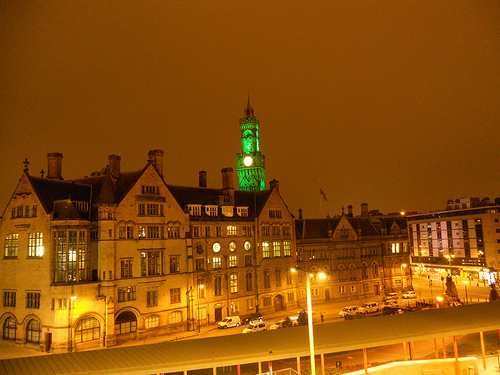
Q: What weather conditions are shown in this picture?
A: It is overcast.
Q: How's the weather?
A: It is overcast.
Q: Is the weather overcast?
A: Yes, it is overcast.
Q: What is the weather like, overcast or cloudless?
A: It is overcast.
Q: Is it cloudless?
A: No, it is overcast.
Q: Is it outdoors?
A: Yes, it is outdoors.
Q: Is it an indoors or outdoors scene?
A: It is outdoors.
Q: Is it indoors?
A: No, it is outdoors.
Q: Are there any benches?
A: No, there are no benches.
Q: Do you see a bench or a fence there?
A: No, there are no benches or fences.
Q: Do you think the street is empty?
A: Yes, the street is empty.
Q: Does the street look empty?
A: Yes, the street is empty.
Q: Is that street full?
A: No, the street is empty.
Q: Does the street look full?
A: No, the street is empty.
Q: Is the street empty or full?
A: The street is empty.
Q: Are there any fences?
A: No, there are no fences.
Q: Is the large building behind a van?
A: Yes, the building is behind a van.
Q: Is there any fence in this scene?
A: No, there are no fences.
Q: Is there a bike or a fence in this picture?
A: No, there are no fences or bikes.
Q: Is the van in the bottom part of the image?
A: Yes, the van is in the bottom of the image.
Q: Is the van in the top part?
A: No, the van is in the bottom of the image.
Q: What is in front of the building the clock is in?
A: The van is in front of the building.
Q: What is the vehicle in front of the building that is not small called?
A: The vehicle is a van.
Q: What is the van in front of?
A: The van is in front of the building.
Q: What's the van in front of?
A: The van is in front of the building.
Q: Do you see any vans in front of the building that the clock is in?
A: Yes, there is a van in front of the building.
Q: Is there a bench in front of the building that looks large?
A: No, there is a van in front of the building.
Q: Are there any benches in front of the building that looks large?
A: No, there is a van in front of the building.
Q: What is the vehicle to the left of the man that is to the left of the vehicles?
A: The vehicle is a van.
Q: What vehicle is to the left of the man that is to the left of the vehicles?
A: The vehicle is a van.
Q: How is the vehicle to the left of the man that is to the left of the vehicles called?
A: The vehicle is a van.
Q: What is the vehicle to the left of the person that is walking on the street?
A: The vehicle is a van.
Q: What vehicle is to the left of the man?
A: The vehicle is a van.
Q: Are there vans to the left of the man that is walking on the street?
A: Yes, there is a van to the left of the man.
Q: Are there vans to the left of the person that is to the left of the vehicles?
A: Yes, there is a van to the left of the man.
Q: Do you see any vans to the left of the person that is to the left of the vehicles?
A: Yes, there is a van to the left of the man.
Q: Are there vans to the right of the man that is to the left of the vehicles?
A: No, the van is to the left of the man.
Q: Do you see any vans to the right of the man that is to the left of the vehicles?
A: No, the van is to the left of the man.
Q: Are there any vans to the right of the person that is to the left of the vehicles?
A: No, the van is to the left of the man.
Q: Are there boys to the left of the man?
A: No, there is a van to the left of the man.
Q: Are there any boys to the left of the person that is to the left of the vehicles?
A: No, there is a van to the left of the man.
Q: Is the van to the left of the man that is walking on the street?
A: Yes, the van is to the left of the man.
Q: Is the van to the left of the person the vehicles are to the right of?
A: Yes, the van is to the left of the man.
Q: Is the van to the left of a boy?
A: No, the van is to the left of the man.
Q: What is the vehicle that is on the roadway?
A: The vehicle is a van.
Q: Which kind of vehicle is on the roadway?
A: The vehicle is a van.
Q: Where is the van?
A: The van is on the roadway.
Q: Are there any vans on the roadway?
A: Yes, there is a van on the roadway.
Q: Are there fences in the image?
A: No, there are no fences.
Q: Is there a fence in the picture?
A: No, there are no fences.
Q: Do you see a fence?
A: No, there are no fences.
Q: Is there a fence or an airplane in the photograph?
A: No, there are no fences or airplanes.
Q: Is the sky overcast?
A: Yes, the sky is overcast.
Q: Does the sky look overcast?
A: Yes, the sky is overcast.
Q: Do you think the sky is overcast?
A: Yes, the sky is overcast.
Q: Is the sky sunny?
A: No, the sky is overcast.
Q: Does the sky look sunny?
A: No, the sky is overcast.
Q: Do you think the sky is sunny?
A: No, the sky is overcast.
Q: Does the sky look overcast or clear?
A: The sky is overcast.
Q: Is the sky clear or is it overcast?
A: The sky is overcast.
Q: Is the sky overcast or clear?
A: The sky is overcast.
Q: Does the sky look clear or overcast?
A: The sky is overcast.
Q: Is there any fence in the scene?
A: No, there are no fences.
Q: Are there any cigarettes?
A: No, there are no cigarettes.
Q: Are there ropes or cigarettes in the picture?
A: No, there are no cigarettes or ropes.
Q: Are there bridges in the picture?
A: Yes, there is a bridge.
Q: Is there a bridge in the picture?
A: Yes, there is a bridge.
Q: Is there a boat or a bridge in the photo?
A: Yes, there is a bridge.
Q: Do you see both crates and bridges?
A: No, there is a bridge but no crates.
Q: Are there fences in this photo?
A: No, there are no fences.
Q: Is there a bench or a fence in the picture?
A: No, there are no fences or benches.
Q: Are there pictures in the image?
A: No, there are no pictures.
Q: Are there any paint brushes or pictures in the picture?
A: No, there are no pictures or paint brushes.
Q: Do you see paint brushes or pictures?
A: No, there are no pictures or paint brushes.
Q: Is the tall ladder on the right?
A: Yes, the ladder is on the right of the image.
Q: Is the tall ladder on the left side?
A: No, the ladder is on the right of the image.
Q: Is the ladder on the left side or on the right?
A: The ladder is on the right of the image.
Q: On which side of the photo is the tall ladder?
A: The ladder is on the right of the image.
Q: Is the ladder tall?
A: Yes, the ladder is tall.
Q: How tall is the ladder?
A: The ladder is tall.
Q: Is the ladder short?
A: No, the ladder is tall.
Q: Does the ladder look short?
A: No, the ladder is tall.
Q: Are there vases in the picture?
A: No, there are no vases.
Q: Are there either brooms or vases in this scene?
A: No, there are no vases or brooms.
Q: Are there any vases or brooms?
A: No, there are no vases or brooms.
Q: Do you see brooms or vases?
A: No, there are no vases or brooms.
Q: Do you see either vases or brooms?
A: No, there are no vases or brooms.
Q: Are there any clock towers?
A: Yes, there is a clock tower.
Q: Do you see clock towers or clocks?
A: Yes, there is a clock tower.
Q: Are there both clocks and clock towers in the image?
A: Yes, there are both a clock tower and a clock.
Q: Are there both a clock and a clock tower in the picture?
A: Yes, there are both a clock tower and a clock.